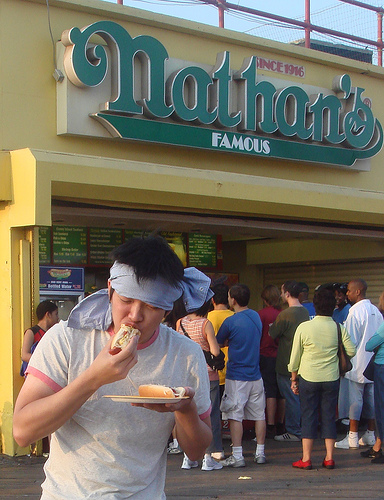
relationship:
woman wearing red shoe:
[281, 283, 357, 471] [294, 457, 312, 470]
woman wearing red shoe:
[281, 283, 357, 471] [322, 458, 335, 467]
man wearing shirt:
[220, 285, 262, 464] [215, 311, 260, 377]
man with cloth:
[52, 270, 177, 496] [105, 267, 174, 299]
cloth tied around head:
[105, 267, 174, 299] [107, 242, 181, 305]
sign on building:
[64, 19, 381, 169] [0, 0, 382, 456]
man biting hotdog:
[10, 230, 214, 492] [109, 324, 135, 353]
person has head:
[10, 240, 210, 500] [105, 238, 183, 343]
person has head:
[173, 300, 223, 471] [187, 297, 214, 316]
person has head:
[52, 240, 214, 491] [110, 235, 178, 286]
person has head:
[339, 279, 377, 415] [341, 277, 371, 297]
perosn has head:
[32, 289, 59, 332] [31, 297, 65, 331]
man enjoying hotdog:
[10, 230, 214, 492] [109, 324, 135, 353]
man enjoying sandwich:
[10, 230, 214, 492] [137, 385, 185, 396]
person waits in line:
[288, 280, 337, 472] [159, 293, 382, 468]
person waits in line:
[217, 279, 272, 468] [159, 293, 382, 468]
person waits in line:
[173, 300, 223, 471] [159, 293, 382, 468]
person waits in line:
[207, 285, 248, 459] [159, 293, 382, 468]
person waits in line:
[359, 290, 382, 460] [159, 293, 382, 468]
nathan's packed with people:
[1, 0, 382, 462] [7, 232, 379, 495]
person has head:
[10, 240, 210, 500] [108, 237, 174, 339]